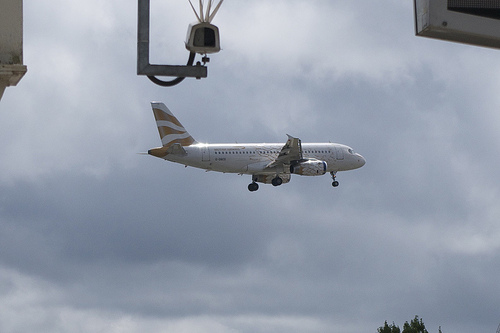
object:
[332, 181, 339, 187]
wheel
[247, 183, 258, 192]
wheel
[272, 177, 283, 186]
wheel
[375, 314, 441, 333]
tree tops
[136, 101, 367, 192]
airplane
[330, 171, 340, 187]
landing gear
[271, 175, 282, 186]
landing gear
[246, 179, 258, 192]
landing gear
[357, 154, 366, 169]
nose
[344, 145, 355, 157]
cockpit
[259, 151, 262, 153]
window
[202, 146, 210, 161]
door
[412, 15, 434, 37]
corner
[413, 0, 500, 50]
sign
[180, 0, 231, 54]
equipment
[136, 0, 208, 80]
bracket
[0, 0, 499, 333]
sky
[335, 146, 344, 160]
door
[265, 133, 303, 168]
wing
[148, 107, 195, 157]
marking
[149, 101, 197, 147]
tail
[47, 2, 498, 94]
clouds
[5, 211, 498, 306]
clouds